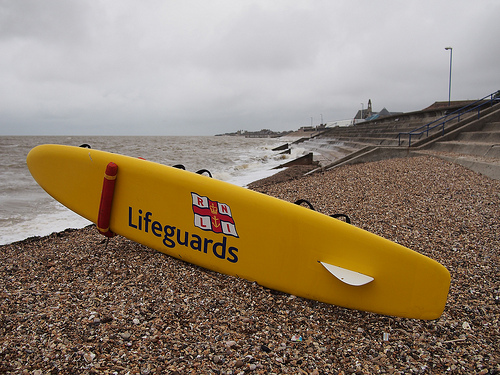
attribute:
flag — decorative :
[190, 195, 239, 236]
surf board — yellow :
[24, 142, 449, 322]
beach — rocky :
[8, 251, 142, 369]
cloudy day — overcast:
[6, 5, 489, 108]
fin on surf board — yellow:
[316, 257, 378, 290]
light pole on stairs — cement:
[442, 43, 457, 116]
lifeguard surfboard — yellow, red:
[24, 136, 455, 323]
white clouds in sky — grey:
[4, 4, 499, 139]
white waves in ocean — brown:
[210, 132, 314, 188]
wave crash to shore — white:
[249, 159, 312, 182]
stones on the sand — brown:
[366, 162, 495, 226]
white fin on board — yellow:
[317, 259, 377, 290]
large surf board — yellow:
[28, 143, 451, 317]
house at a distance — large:
[349, 94, 399, 125]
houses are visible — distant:
[274, 94, 499, 177]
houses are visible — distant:
[293, 87, 500, 134]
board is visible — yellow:
[22, 131, 452, 324]